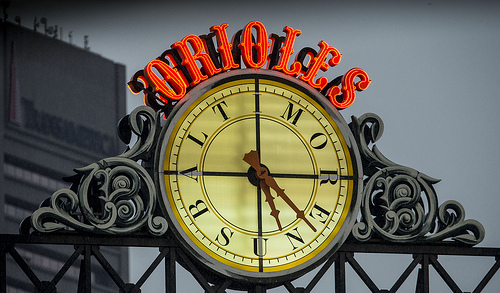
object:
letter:
[145, 59, 185, 101]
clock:
[148, 67, 364, 286]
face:
[165, 78, 353, 273]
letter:
[280, 100, 306, 127]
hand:
[241, 150, 317, 231]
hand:
[260, 181, 282, 233]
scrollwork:
[347, 111, 487, 246]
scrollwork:
[16, 105, 170, 239]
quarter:
[163, 78, 260, 176]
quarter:
[257, 77, 352, 177]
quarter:
[165, 173, 261, 272]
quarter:
[259, 177, 358, 273]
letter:
[126, 69, 168, 113]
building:
[2, 19, 132, 292]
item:
[82, 31, 90, 50]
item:
[14, 13, 22, 27]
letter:
[214, 226, 235, 247]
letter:
[185, 131, 207, 149]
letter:
[328, 67, 371, 110]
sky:
[2, 0, 500, 291]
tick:
[264, 87, 267, 92]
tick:
[317, 117, 322, 120]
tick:
[224, 250, 227, 255]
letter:
[239, 20, 271, 70]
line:
[253, 77, 268, 272]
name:
[144, 20, 371, 111]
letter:
[309, 131, 330, 149]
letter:
[319, 167, 338, 186]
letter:
[309, 201, 332, 225]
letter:
[284, 226, 305, 251]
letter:
[251, 235, 268, 257]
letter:
[188, 199, 210, 221]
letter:
[299, 40, 341, 89]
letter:
[180, 163, 199, 184]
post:
[333, 252, 346, 293]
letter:
[172, 34, 222, 86]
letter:
[209, 23, 241, 71]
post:
[164, 247, 176, 292]